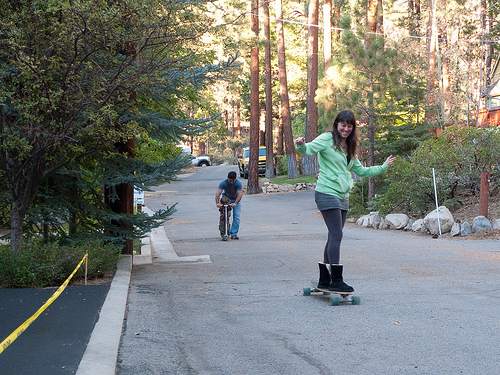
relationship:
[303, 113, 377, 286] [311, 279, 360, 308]
woman riding skateboard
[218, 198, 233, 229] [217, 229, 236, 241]
kid riding scooter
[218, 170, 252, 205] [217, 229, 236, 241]
man riding scooter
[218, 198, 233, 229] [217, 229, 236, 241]
kid on scooter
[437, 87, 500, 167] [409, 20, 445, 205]
house on side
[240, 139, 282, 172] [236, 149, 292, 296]
truck on road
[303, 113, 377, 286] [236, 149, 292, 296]
lady on road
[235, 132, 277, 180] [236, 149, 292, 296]
car in road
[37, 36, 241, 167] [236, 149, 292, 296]
trees on road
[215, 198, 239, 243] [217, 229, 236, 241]
boy on scooter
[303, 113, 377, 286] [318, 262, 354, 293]
lady wears shoes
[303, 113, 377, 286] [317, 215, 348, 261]
lady wears pants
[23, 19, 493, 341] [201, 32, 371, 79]
picture in daytime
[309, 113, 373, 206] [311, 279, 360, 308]
girl riding skateboard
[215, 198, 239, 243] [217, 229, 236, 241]
boy riding scooter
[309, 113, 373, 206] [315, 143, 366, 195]
girl wearing jacket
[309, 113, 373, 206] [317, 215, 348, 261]
girl wearing leggings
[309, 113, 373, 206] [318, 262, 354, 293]
girl wearing boots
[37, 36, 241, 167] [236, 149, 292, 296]
trees next to road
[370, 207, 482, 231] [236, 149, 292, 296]
rocks along road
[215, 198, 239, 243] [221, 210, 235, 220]
boy wearing shirt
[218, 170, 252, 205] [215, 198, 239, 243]
man helping boy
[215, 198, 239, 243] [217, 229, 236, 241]
boy ride scooter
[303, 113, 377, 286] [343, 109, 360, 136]
woman has hair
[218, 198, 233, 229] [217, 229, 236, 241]
child on scooter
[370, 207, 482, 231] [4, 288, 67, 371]
rocks on driveway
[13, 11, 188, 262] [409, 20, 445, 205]
tree on side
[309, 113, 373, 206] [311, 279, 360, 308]
girl on skateboard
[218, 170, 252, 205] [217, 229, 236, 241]
man on scooter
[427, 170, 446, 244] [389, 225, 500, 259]
post on ground